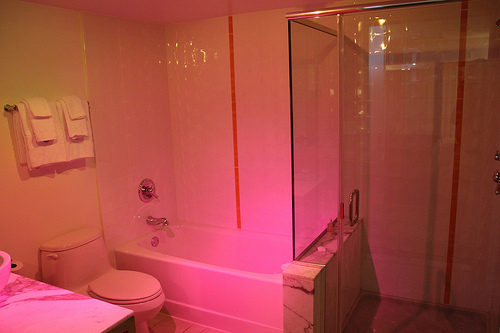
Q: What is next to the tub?
A: Toilet.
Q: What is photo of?
A: Enclosed shower.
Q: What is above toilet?
A: Towels.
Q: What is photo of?
A: Bathroom.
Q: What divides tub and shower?
A: Marble wall.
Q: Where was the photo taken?
A: Bathroom.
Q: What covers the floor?
A: Tile.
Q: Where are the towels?
A: Hanging above toilet.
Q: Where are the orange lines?
A: In shower and bath.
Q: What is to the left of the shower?
A: Bathtub.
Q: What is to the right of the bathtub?
A: Shower.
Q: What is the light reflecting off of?
A: Shower and bath walls.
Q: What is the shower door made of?
A: Glass.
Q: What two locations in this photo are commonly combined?
A: Bathtub and shower.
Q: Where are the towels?
A: On the towel bar.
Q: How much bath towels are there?
A: Two.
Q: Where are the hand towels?
A: On the bath towels.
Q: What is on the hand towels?
A: Wash cloths.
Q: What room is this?
A: Bathroom.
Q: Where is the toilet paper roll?
A: Right of the toilet.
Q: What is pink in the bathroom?
A: The light.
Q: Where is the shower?
A: Next to the bathtub.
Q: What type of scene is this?
A: Indoor.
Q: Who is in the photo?
A: No one.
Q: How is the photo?
A: Clear.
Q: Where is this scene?
A: Bathroom.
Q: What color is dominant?
A: White.